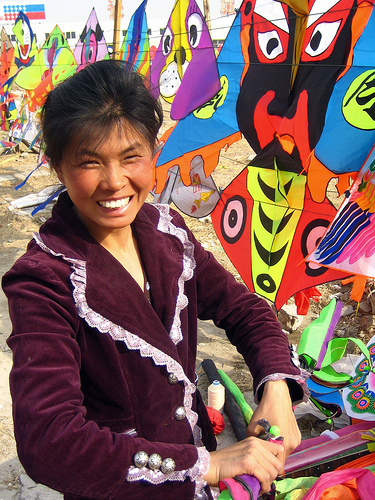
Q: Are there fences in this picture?
A: No, there are no fences.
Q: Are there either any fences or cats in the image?
A: No, there are no fences or cats.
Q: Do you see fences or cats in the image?
A: No, there are no fences or cats.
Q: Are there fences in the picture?
A: No, there are no fences.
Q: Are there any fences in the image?
A: No, there are no fences.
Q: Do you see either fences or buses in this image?
A: No, there are no fences or buses.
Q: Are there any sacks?
A: No, there are no sacks.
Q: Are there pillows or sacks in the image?
A: No, there are no sacks or pillows.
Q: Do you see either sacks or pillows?
A: No, there are no sacks or pillows.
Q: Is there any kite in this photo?
A: Yes, there is a kite.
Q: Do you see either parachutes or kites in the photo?
A: Yes, there is a kite.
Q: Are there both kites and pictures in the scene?
A: Yes, there are both a kite and a picture.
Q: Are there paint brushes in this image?
A: No, there are no paint brushes.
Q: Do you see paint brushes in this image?
A: No, there are no paint brushes.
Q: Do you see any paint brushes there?
A: No, there are no paint brushes.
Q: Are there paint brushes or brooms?
A: No, there are no paint brushes or brooms.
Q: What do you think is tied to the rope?
A: The kite is tied to the rope.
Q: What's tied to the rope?
A: The kite is tied to the rope.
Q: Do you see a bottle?
A: Yes, there is a bottle.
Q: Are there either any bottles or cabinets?
A: Yes, there is a bottle.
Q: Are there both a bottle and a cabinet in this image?
A: No, there is a bottle but no cabinets.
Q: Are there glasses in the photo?
A: No, there are no glasses.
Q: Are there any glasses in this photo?
A: No, there are no glasses.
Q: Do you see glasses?
A: No, there are no glasses.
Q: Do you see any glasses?
A: No, there are no glasses.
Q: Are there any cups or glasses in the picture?
A: No, there are no glasses or cups.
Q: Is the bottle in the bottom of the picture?
A: Yes, the bottle is in the bottom of the image.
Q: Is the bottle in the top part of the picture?
A: No, the bottle is in the bottom of the image.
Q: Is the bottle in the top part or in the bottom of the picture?
A: The bottle is in the bottom of the image.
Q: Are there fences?
A: No, there are no fences.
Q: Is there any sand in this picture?
A: Yes, there is sand.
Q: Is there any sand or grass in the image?
A: Yes, there is sand.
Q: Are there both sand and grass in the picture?
A: No, there is sand but no grass.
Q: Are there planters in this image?
A: No, there are no planters.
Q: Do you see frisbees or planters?
A: No, there are no planters or frisbees.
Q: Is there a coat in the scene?
A: Yes, there is a coat.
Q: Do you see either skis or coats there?
A: Yes, there is a coat.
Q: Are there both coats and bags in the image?
A: No, there is a coat but no bags.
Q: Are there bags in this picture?
A: No, there are no bags.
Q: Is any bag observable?
A: No, there are no bags.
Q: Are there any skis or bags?
A: No, there are no bags or skis.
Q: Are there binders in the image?
A: No, there are no binders.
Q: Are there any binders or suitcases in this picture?
A: No, there are no binders or suitcases.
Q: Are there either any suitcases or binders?
A: No, there are no binders or suitcases.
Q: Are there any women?
A: Yes, there is a woman.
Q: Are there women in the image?
A: Yes, there is a woman.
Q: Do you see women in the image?
A: Yes, there is a woman.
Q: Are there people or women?
A: Yes, there is a woman.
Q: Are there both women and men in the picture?
A: No, there is a woman but no men.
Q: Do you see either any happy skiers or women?
A: Yes, there is a happy woman.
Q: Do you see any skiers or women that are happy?
A: Yes, the woman is happy.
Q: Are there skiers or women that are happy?
A: Yes, the woman is happy.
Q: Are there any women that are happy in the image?
A: Yes, there is a happy woman.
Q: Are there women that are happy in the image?
A: Yes, there is a happy woman.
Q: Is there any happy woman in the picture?
A: Yes, there is a happy woman.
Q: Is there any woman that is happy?
A: Yes, there is a woman that is happy.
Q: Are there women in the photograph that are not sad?
A: Yes, there is a happy woman.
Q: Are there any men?
A: No, there are no men.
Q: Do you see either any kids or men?
A: No, there are no men or kids.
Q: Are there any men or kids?
A: No, there are no men or kids.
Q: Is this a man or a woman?
A: This is a woman.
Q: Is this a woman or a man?
A: This is a woman.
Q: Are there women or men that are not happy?
A: No, there is a woman but she is happy.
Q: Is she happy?
A: Yes, the woman is happy.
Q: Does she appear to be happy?
A: Yes, the woman is happy.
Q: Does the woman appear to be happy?
A: Yes, the woman is happy.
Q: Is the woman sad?
A: No, the woman is happy.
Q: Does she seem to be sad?
A: No, the woman is happy.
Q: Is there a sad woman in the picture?
A: No, there is a woman but she is happy.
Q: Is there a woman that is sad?
A: No, there is a woman but she is happy.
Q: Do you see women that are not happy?
A: No, there is a woman but she is happy.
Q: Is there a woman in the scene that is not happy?
A: No, there is a woman but she is happy.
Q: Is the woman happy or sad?
A: The woman is happy.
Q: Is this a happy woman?
A: Yes, this is a happy woman.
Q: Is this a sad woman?
A: No, this is a happy woman.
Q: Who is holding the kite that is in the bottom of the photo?
A: The woman is holding the kite.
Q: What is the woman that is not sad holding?
A: The woman is holding the kite.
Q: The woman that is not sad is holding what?
A: The woman is holding the kite.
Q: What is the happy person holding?
A: The woman is holding the kite.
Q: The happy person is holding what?
A: The woman is holding the kite.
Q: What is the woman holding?
A: The woman is holding the kite.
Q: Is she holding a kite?
A: Yes, the woman is holding a kite.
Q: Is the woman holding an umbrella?
A: No, the woman is holding a kite.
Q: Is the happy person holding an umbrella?
A: No, the woman is holding a kite.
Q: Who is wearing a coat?
A: The woman is wearing a coat.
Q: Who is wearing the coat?
A: The woman is wearing a coat.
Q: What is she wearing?
A: The woman is wearing a coat.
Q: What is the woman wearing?
A: The woman is wearing a coat.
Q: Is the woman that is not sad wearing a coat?
A: Yes, the woman is wearing a coat.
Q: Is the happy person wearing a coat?
A: Yes, the woman is wearing a coat.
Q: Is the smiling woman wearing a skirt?
A: No, the woman is wearing a coat.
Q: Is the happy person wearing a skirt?
A: No, the woman is wearing a coat.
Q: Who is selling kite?
A: The woman is selling kite.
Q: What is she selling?
A: The woman is selling kite.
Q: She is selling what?
A: The woman is selling kite.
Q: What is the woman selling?
A: The woman is selling kite.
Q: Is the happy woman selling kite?
A: Yes, the woman is selling kite.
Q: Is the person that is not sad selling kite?
A: Yes, the woman is selling kite.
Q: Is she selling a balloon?
A: No, the woman is selling kite.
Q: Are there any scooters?
A: No, there are no scooters.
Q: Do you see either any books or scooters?
A: No, there are no scooters or books.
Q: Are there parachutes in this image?
A: No, there are no parachutes.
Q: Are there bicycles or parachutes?
A: No, there are no parachutes or bicycles.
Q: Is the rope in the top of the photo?
A: Yes, the rope is in the top of the image.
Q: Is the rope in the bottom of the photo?
A: No, the rope is in the top of the image.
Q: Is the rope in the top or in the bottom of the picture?
A: The rope is in the top of the image.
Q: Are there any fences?
A: No, there are no fences.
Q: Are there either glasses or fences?
A: No, there are no fences or glasses.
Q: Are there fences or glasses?
A: No, there are no fences or glasses.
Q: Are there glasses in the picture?
A: No, there are no glasses.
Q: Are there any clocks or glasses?
A: No, there are no glasses or clocks.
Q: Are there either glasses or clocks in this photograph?
A: No, there are no glasses or clocks.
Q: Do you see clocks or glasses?
A: No, there are no glasses or clocks.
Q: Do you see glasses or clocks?
A: No, there are no glasses or clocks.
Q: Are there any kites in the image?
A: Yes, there is a kite.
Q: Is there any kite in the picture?
A: Yes, there is a kite.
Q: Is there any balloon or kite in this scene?
A: Yes, there is a kite.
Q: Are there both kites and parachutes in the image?
A: No, there is a kite but no parachutes.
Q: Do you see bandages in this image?
A: No, there are no bandages.